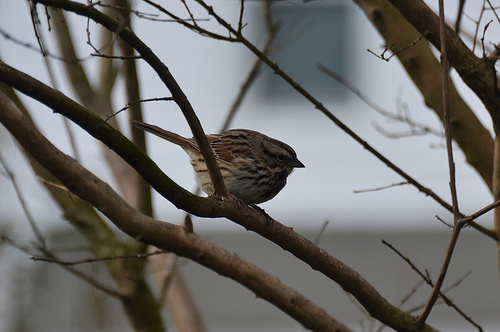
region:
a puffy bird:
[165, 126, 310, 208]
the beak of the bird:
[291, 158, 307, 170]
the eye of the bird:
[273, 150, 285, 160]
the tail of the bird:
[130, 108, 200, 155]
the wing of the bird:
[206, 133, 268, 164]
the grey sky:
[291, 108, 330, 153]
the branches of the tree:
[1, 2, 199, 325]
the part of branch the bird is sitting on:
[203, 190, 307, 250]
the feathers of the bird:
[219, 138, 274, 189]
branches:
[374, 205, 451, 328]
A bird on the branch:
[138, 120, 305, 199]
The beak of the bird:
[294, 158, 306, 165]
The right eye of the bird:
[275, 150, 286, 160]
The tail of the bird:
[130, 118, 184, 145]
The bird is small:
[137, 119, 303, 203]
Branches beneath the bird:
[1, 62, 432, 330]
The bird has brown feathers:
[135, 122, 304, 199]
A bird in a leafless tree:
[0, 0, 498, 330]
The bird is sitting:
[133, 118, 303, 205]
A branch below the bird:
[3, 60, 427, 330]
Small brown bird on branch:
[141, 99, 348, 231]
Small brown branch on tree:
[370, 214, 476, 324]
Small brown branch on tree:
[260, 217, 392, 319]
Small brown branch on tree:
[212, 247, 303, 305]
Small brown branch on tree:
[95, 176, 217, 288]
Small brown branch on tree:
[45, 89, 182, 189]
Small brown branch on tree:
[401, 9, 498, 150]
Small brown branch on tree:
[245, 39, 430, 154]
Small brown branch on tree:
[23, 9, 235, 95]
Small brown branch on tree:
[82, 259, 173, 328]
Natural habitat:
[1, 2, 496, 327]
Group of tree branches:
[0, 1, 495, 331]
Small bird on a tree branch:
[132, 115, 304, 212]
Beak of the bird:
[292, 156, 304, 171]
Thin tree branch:
[138, 1, 495, 248]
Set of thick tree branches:
[348, 2, 496, 194]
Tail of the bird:
[130, 119, 190, 153]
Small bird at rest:
[132, 118, 306, 210]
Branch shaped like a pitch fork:
[1, 2, 439, 330]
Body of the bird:
[187, 126, 304, 203]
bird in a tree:
[129, 108, 313, 222]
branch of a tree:
[83, 174, 145, 233]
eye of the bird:
[267, 149, 287, 165]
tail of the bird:
[125, 106, 193, 153]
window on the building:
[257, 4, 351, 102]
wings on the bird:
[205, 135, 238, 172]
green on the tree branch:
[65, 210, 111, 250]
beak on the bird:
[290, 158, 305, 172]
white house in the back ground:
[307, 142, 345, 179]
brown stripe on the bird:
[226, 129, 248, 143]